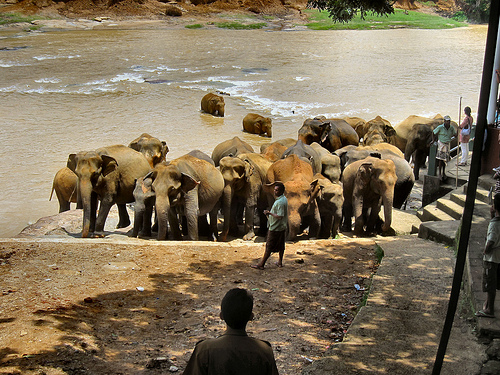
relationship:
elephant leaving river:
[129, 129, 170, 167] [0, 24, 484, 234]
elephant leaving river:
[47, 166, 77, 212] [0, 24, 484, 234]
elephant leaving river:
[129, 155, 224, 239] [0, 24, 484, 234]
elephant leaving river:
[216, 150, 277, 237] [0, 24, 484, 234]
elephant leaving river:
[240, 111, 274, 139] [0, 24, 484, 234]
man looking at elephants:
[480, 197, 497, 242] [113, 120, 419, 220]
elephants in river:
[195, 84, 276, 140] [4, 29, 436, 147]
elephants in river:
[201, 92, 280, 140] [5, 26, 472, 274]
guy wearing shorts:
[258, 181, 290, 272] [267, 230, 284, 254]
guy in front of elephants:
[258, 181, 290, 272] [44, 86, 481, 226]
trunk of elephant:
[76, 175, 93, 236] [63, 149, 149, 240]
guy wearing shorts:
[248, 181, 289, 271] [263, 225, 286, 252]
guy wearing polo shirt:
[248, 181, 289, 271] [266, 192, 289, 232]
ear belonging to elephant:
[65, 152, 77, 172] [65, 143, 154, 238]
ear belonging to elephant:
[98, 151, 118, 186] [65, 143, 154, 238]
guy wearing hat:
[430, 114, 459, 179] [441, 113, 451, 123]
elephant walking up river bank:
[65, 143, 154, 238] [1, 209, 471, 371]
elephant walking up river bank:
[141, 153, 225, 241] [1, 209, 471, 371]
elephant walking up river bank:
[215, 148, 272, 241] [1, 209, 471, 371]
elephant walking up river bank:
[263, 152, 323, 245] [1, 209, 471, 371]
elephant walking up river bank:
[340, 150, 400, 238] [1, 209, 471, 371]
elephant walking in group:
[65, 143, 154, 238] [45, 89, 459, 241]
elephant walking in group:
[141, 153, 225, 241] [45, 89, 459, 241]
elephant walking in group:
[215, 148, 272, 241] [45, 89, 459, 241]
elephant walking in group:
[263, 152, 323, 245] [45, 89, 459, 241]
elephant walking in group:
[340, 150, 400, 238] [45, 89, 459, 241]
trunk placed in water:
[218, 107, 225, 117] [0, 22, 482, 234]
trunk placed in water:
[265, 130, 272, 138] [0, 22, 482, 234]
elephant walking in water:
[199, 90, 226, 117] [0, 22, 482, 234]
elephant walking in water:
[241, 111, 272, 137] [0, 22, 482, 234]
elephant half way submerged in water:
[199, 90, 226, 117] [0, 22, 482, 234]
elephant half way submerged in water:
[241, 111, 272, 137] [0, 22, 482, 234]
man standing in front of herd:
[248, 180, 290, 271] [47, 89, 460, 240]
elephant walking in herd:
[65, 143, 154, 238] [47, 89, 460, 240]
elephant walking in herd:
[141, 153, 225, 241] [47, 89, 460, 240]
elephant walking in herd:
[215, 148, 272, 241] [47, 89, 460, 240]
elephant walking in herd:
[261, 150, 323, 237] [47, 89, 460, 240]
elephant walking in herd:
[340, 150, 400, 238] [47, 89, 460, 240]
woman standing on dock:
[454, 104, 474, 167] [439, 146, 474, 186]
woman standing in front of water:
[454, 104, 474, 167] [0, 22, 482, 234]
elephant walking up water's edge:
[65, 143, 154, 238] [1, 207, 423, 255]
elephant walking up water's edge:
[141, 153, 225, 241] [1, 207, 423, 255]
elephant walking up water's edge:
[215, 148, 272, 241] [1, 207, 423, 255]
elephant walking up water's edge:
[261, 150, 323, 237] [1, 207, 423, 255]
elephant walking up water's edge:
[339, 154, 399, 234] [1, 207, 423, 255]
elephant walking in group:
[261, 150, 323, 237] [45, 89, 459, 241]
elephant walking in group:
[339, 154, 399, 234] [45, 89, 459, 241]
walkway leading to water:
[310, 201, 484, 372] [0, 22, 482, 234]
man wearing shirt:
[432, 112, 460, 178] [430, 121, 459, 143]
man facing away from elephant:
[432, 112, 460, 178] [65, 143, 154, 238]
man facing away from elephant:
[432, 112, 460, 178] [141, 153, 225, 241]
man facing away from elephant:
[432, 112, 460, 178] [215, 148, 272, 241]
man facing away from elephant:
[432, 112, 460, 178] [265, 151, 324, 239]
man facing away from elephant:
[432, 112, 460, 178] [339, 154, 399, 234]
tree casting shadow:
[304, 0, 396, 23] [2, 232, 480, 372]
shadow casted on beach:
[2, 232, 480, 372] [1, 240, 381, 372]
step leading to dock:
[419, 201, 457, 224] [441, 147, 474, 188]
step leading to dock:
[435, 196, 465, 220] [441, 147, 474, 188]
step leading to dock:
[450, 190, 485, 210] [441, 147, 474, 188]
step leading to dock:
[463, 182, 484, 202] [441, 147, 474, 188]